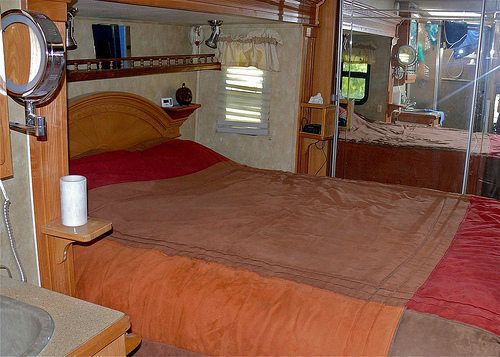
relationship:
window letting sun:
[218, 65, 268, 130] [225, 65, 261, 120]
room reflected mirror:
[4, 7, 484, 343] [336, 0, 499, 202]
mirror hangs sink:
[336, 0, 500, 200] [1, 276, 130, 350]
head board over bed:
[69, 90, 183, 150] [76, 135, 498, 355]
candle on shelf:
[62, 170, 83, 225] [42, 210, 114, 255]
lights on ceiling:
[61, 13, 224, 50] [70, 5, 303, 26]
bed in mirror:
[340, 103, 498, 185] [336, 0, 499, 202]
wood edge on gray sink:
[1, 272, 126, 355] [1, 293, 52, 355]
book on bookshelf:
[97, 25, 122, 60] [66, 52, 223, 84]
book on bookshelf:
[118, 20, 130, 66] [66, 52, 223, 84]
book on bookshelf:
[124, 23, 141, 70] [66, 52, 223, 84]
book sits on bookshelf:
[90, 22, 123, 70] [65, 53, 225, 81]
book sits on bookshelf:
[118, 23, 128, 69] [65, 53, 225, 81]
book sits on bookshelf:
[125, 25, 132, 69] [65, 53, 225, 81]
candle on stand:
[58, 173, 90, 228] [41, 216, 113, 264]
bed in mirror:
[335, 102, 500, 199] [336, 0, 499, 202]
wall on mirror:
[336, 7, 482, 195] [5, 11, 55, 101]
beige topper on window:
[189, 25, 284, 72] [211, 58, 281, 132]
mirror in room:
[336, 0, 499, 202] [15, 1, 377, 349]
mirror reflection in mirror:
[387, 37, 420, 94] [336, 0, 499, 202]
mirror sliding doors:
[336, 0, 500, 200] [347, 10, 485, 154]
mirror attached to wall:
[3, 17, 60, 152] [186, 37, 286, 147]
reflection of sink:
[406, 97, 442, 117] [4, 264, 108, 354]